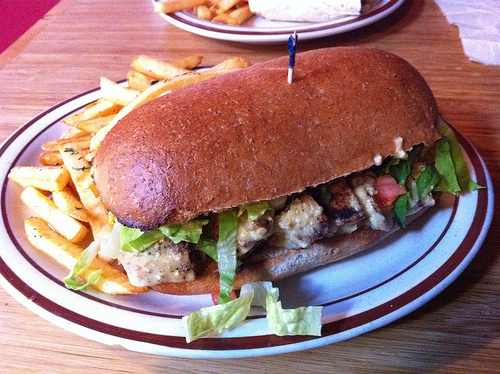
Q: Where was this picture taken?
A: A restaurant.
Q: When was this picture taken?
A: During the day.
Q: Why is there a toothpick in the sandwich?
A: To hold it together.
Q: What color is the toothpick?
A: Blue.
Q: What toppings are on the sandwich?
A: Lettuce and tomato.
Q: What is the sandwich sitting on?
A: A plate.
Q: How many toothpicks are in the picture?
A: One.